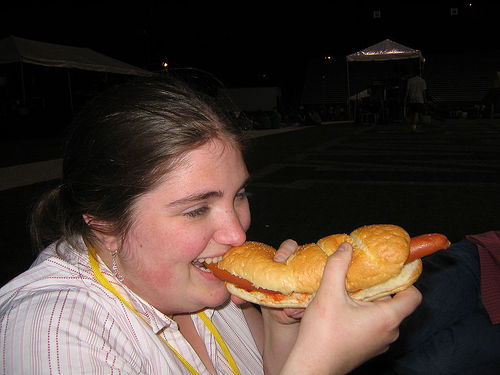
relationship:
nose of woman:
[216, 206, 261, 263] [61, 109, 381, 344]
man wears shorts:
[397, 70, 434, 130] [400, 95, 430, 116]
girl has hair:
[0, 72, 422, 375] [19, 77, 241, 259]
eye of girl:
[182, 205, 209, 219] [0, 72, 422, 375]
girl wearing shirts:
[0, 72, 422, 375] [1, 215, 262, 372]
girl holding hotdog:
[0, 72, 422, 375] [211, 222, 449, 311]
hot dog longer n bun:
[198, 233, 451, 295] [223, 223, 423, 307]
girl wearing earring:
[2, 95, 421, 368] [96, 236, 136, 297]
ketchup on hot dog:
[250, 284, 315, 304] [207, 238, 453, 308]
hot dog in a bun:
[198, 223, 463, 314] [227, 219, 418, 296]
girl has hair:
[2, 95, 421, 368] [32, 80, 232, 235]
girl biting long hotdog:
[2, 95, 421, 368] [203, 259, 249, 290]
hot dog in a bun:
[198, 233, 451, 295] [212, 235, 412, 292]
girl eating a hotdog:
[2, 95, 421, 368] [211, 222, 449, 311]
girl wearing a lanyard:
[2, 95, 421, 368] [76, 227, 238, 372]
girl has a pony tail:
[0, 72, 422, 375] [20, 171, 76, 256]